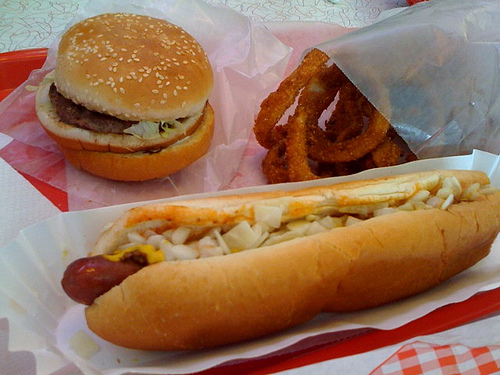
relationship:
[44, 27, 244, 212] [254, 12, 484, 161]
hamburger next to onion rings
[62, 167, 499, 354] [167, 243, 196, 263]
hot dog with onion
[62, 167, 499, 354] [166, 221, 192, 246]
hot dog with onion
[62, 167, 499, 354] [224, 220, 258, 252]
hot dog with onion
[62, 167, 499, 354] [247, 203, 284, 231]
hot dog with onion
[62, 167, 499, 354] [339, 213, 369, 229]
hot dog with onion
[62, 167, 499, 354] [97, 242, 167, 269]
hot dog with mustard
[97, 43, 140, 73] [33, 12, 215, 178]
seeds on bun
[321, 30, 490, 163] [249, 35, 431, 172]
bag holds food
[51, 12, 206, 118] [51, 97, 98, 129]
bun on hamburger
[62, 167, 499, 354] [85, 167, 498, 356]
hot dog on roll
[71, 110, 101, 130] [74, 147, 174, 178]
sausage on roll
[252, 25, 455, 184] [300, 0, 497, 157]
onion rings in bag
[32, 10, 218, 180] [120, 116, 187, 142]
burger has lettuce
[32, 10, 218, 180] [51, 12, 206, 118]
burger on bun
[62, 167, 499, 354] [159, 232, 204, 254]
hot dog has onions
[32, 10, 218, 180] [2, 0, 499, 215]
burger on wrapper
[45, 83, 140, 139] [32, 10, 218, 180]
burger pattie on burger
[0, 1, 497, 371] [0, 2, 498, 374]
white paper on tray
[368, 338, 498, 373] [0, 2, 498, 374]
checkered cloth on tray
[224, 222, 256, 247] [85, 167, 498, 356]
onion on roll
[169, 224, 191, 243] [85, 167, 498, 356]
onion on roll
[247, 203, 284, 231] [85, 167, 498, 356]
onion on roll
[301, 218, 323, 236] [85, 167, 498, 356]
onion on roll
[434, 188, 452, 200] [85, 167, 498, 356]
onion on roll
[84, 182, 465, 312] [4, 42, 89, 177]
food on tray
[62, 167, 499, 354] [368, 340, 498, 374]
hot dog on paper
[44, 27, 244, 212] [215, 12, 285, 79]
hamburger on clear paper